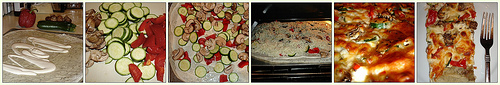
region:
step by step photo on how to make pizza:
[1, 0, 495, 84]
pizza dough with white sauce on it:
[9, 28, 62, 83]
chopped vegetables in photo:
[86, 6, 163, 80]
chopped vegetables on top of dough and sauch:
[174, 14, 249, 84]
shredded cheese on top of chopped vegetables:
[255, 15, 321, 84]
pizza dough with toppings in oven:
[261, 14, 356, 76]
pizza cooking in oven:
[343, 8, 419, 79]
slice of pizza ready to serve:
[418, 11, 495, 78]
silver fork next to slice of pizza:
[431, 4, 495, 68]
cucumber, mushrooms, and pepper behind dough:
[16, 4, 83, 63]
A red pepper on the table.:
[13, 4, 41, 36]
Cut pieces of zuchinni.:
[107, 3, 137, 63]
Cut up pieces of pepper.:
[136, 18, 165, 76]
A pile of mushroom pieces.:
[86, 8, 102, 74]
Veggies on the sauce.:
[176, 5, 247, 79]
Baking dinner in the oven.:
[256, 18, 329, 65]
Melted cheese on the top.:
[338, 5, 408, 77]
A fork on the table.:
[482, 12, 498, 84]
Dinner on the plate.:
[425, 5, 477, 80]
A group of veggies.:
[16, 6, 79, 33]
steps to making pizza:
[2, 6, 495, 78]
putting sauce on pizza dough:
[8, 7, 75, 74]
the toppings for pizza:
[90, 7, 160, 77]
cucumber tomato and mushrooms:
[90, 6, 159, 73]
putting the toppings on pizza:
[176, 5, 239, 73]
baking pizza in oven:
[261, 4, 331, 84]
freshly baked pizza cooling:
[337, 11, 404, 76]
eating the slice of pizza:
[419, 9, 493, 75]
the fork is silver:
[470, 10, 497, 45]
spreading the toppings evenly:
[176, 6, 238, 78]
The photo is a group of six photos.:
[0, 2, 498, 83]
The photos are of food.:
[1, 0, 496, 82]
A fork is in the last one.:
[473, 7, 497, 82]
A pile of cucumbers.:
[93, 9, 145, 67]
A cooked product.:
[337, 7, 408, 76]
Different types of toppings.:
[173, 4, 243, 76]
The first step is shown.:
[5, 10, 78, 83]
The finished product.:
[423, 4, 481, 76]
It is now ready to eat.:
[421, 5, 481, 72]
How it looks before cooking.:
[254, 11, 326, 73]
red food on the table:
[8, 5, 48, 32]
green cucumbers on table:
[98, 6, 145, 60]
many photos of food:
[17, 12, 470, 80]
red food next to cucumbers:
[142, 17, 164, 59]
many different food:
[172, 10, 233, 64]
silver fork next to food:
[473, 12, 498, 68]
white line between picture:
[155, 3, 179, 80]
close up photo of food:
[333, 8, 400, 76]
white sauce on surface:
[13, 34, 63, 84]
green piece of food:
[40, 11, 78, 42]